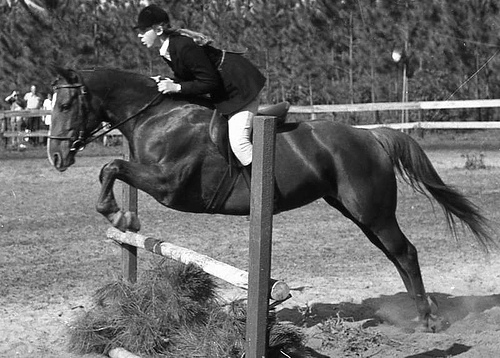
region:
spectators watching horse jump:
[1, 78, 56, 127]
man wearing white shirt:
[23, 80, 43, 122]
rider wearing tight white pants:
[223, 75, 280, 162]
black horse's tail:
[370, 114, 491, 260]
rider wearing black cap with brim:
[119, 5, 181, 30]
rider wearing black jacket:
[135, 13, 276, 105]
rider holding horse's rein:
[125, 8, 207, 108]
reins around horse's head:
[46, 63, 94, 172]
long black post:
[242, 102, 284, 356]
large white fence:
[329, 83, 499, 138]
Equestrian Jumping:
[31, 1, 487, 331]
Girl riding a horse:
[31, 2, 495, 334]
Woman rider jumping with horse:
[125, 6, 282, 191]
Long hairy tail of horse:
[371, 121, 497, 227]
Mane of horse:
[85, 61, 161, 87]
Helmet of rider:
[126, 0, 174, 28]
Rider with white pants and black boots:
[131, 1, 287, 218]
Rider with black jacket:
[120, 0, 293, 210]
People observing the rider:
[6, 85, 54, 146]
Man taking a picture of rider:
[3, 83, 26, 143]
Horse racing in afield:
[5, 2, 494, 350]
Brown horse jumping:
[49, 65, 499, 330]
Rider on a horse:
[131, 3, 308, 221]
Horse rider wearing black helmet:
[131, 5, 284, 195]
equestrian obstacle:
[105, 107, 285, 357]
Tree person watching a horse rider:
[6, 82, 56, 150]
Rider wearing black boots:
[126, 5, 294, 224]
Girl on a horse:
[36, 2, 491, 332]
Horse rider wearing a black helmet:
[126, 1, 319, 208]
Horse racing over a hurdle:
[17, 0, 487, 341]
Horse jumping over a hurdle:
[31, 53, 496, 331]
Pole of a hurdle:
[238, 109, 283, 356]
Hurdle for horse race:
[92, 102, 306, 356]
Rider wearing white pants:
[130, 2, 294, 217]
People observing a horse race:
[1, 82, 61, 148]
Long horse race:
[368, 120, 498, 261]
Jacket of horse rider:
[161, 30, 270, 120]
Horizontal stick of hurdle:
[92, 220, 302, 307]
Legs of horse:
[327, 161, 452, 335]